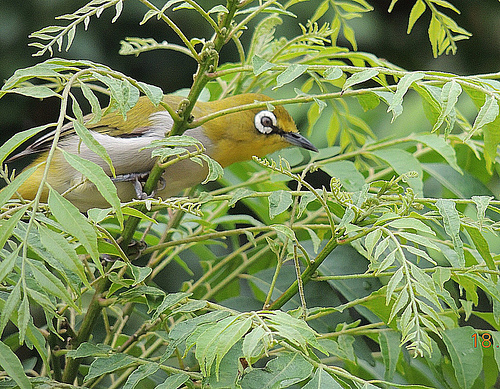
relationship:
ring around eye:
[254, 110, 277, 136] [261, 118, 273, 128]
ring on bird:
[254, 110, 277, 136] [0, 90, 322, 214]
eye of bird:
[261, 118, 273, 128] [0, 90, 322, 214]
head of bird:
[206, 90, 321, 170] [0, 90, 322, 214]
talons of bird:
[109, 171, 168, 202] [0, 90, 322, 214]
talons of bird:
[98, 238, 149, 267] [0, 90, 322, 214]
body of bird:
[46, 88, 223, 216] [0, 90, 322, 214]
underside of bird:
[58, 108, 220, 214] [0, 90, 322, 214]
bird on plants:
[0, 90, 322, 214] [3, 0, 498, 388]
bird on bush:
[0, 90, 322, 214] [3, 0, 498, 388]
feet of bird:
[101, 168, 166, 266] [0, 90, 322, 214]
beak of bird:
[286, 132, 320, 153] [0, 90, 322, 214]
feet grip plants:
[101, 168, 166, 266] [50, 0, 250, 388]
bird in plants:
[0, 90, 322, 214] [3, 0, 498, 388]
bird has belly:
[0, 90, 322, 214] [58, 108, 220, 214]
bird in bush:
[0, 90, 322, 214] [3, 0, 498, 388]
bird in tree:
[0, 90, 322, 214] [3, 0, 498, 388]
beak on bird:
[286, 132, 320, 153] [0, 90, 322, 214]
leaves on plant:
[361, 207, 448, 365] [3, 0, 498, 388]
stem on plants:
[50, 0, 250, 388] [3, 0, 498, 388]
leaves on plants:
[361, 207, 448, 365] [3, 0, 498, 388]